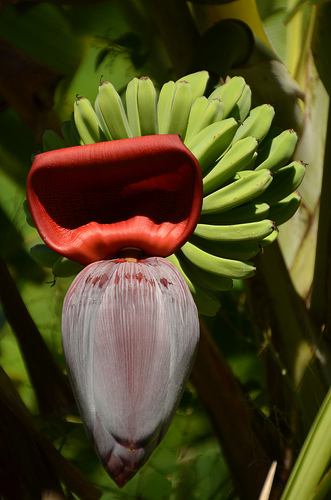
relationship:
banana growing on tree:
[73, 70, 305, 319] [0, 0, 330, 498]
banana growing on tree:
[73, 70, 305, 319] [187, 260, 308, 496]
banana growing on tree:
[92, 73, 131, 141] [187, 260, 308, 496]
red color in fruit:
[23, 131, 203, 488] [23, 65, 313, 491]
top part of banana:
[42, 131, 226, 258] [68, 71, 284, 178]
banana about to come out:
[73, 70, 305, 319] [103, 211, 234, 262]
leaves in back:
[171, 431, 213, 479] [26, 293, 65, 365]